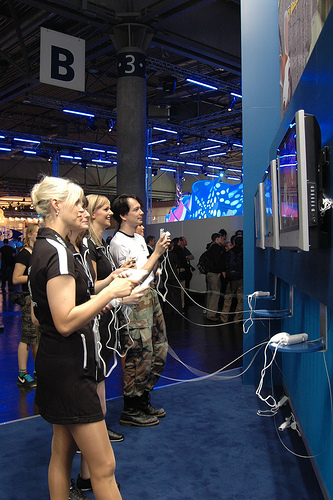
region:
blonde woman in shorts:
[31, 177, 137, 495]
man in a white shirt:
[111, 196, 165, 424]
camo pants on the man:
[117, 288, 168, 395]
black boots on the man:
[119, 391, 166, 425]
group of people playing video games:
[28, 176, 164, 498]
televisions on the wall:
[252, 109, 330, 250]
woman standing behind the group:
[13, 226, 45, 387]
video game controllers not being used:
[244, 290, 303, 443]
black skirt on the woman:
[33, 335, 105, 423]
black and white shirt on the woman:
[30, 229, 93, 333]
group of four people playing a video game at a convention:
[7, 161, 216, 493]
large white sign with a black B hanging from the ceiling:
[37, 26, 91, 95]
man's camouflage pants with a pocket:
[117, 298, 171, 407]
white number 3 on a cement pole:
[116, 52, 143, 77]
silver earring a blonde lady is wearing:
[54, 208, 62, 215]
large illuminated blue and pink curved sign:
[164, 170, 247, 223]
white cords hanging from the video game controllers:
[165, 346, 277, 394]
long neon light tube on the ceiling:
[59, 105, 100, 122]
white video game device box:
[270, 328, 309, 345]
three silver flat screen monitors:
[237, 114, 322, 260]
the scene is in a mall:
[28, 21, 314, 497]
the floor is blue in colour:
[161, 420, 240, 497]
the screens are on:
[251, 120, 314, 258]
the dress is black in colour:
[32, 222, 131, 424]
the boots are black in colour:
[115, 385, 172, 434]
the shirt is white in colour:
[115, 227, 170, 286]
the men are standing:
[189, 213, 240, 320]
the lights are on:
[116, 114, 223, 181]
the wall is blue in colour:
[252, 18, 279, 131]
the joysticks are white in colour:
[53, 230, 188, 320]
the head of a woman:
[25, 176, 103, 240]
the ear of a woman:
[46, 190, 67, 226]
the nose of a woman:
[76, 198, 89, 213]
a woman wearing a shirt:
[28, 229, 133, 355]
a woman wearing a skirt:
[35, 309, 147, 436]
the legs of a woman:
[36, 356, 217, 492]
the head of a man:
[118, 186, 161, 236]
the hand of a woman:
[96, 279, 150, 310]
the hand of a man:
[152, 225, 185, 264]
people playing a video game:
[32, 166, 215, 378]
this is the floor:
[181, 332, 231, 362]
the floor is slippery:
[188, 333, 234, 360]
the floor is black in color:
[189, 329, 229, 355]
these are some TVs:
[238, 112, 321, 260]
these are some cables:
[118, 219, 268, 366]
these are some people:
[26, 170, 172, 427]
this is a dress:
[43, 345, 68, 402]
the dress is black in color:
[50, 370, 77, 408]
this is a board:
[43, 36, 86, 84]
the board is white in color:
[74, 41, 85, 54]